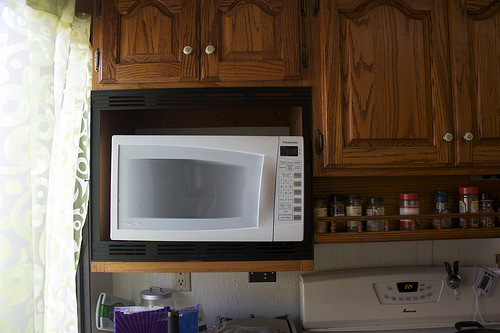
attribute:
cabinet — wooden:
[324, 5, 487, 162]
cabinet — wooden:
[106, 2, 305, 88]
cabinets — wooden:
[45, 10, 485, 243]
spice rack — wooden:
[312, 185, 498, 242]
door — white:
[88, 11, 229, 103]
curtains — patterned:
[7, 12, 91, 332]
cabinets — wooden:
[90, 0, 498, 175]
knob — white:
[464, 131, 473, 140]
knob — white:
[442, 131, 453, 141]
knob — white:
[204, 45, 215, 54]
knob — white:
[183, 45, 193, 54]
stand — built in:
[89, 90, 314, 272]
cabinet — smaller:
[91, 0, 310, 91]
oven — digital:
[295, 256, 498, 330]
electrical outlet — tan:
[147, 265, 219, 313]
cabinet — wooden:
[320, 27, 462, 169]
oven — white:
[301, 266, 498, 328]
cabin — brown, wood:
[244, 37, 482, 219]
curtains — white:
[1, 2, 92, 332]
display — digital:
[278, 144, 303, 225]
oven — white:
[109, 124, 304, 243]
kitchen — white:
[7, 7, 499, 327]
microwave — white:
[107, 133, 304, 243]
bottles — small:
[315, 187, 498, 232]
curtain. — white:
[9, 6, 135, 330]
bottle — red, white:
[381, 190, 431, 234]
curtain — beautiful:
[2, 1, 92, 331]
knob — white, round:
[442, 130, 455, 142]